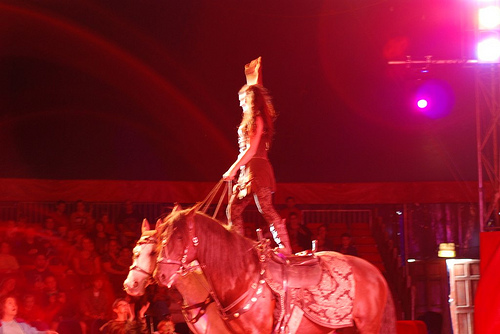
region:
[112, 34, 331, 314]
woman standing on the horses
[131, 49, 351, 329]
woman standing on the horses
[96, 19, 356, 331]
woman standing on the horses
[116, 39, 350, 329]
woman standing on the horses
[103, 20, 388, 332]
woman standing on the horses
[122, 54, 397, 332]
Costumed woman standing on backs of two horses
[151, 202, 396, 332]
Brown horse wearing elaborate tack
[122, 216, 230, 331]
White horse with fancy bridle standing behind brown horse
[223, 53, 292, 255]
Trick rider performing in front of audience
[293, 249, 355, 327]
Blanket with metallic pattern under horse's saddle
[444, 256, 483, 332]
Brown paneled wooden door in background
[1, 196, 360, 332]
Indistinct crowd of people sitting on bleachers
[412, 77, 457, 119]
Spotlight with purple halo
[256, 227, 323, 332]
Special trick rider's saddle on brown horse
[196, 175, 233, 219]
Reins to horses' bridles held in performer's hands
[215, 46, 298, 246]
woman wearing a skirt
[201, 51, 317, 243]
woman with hand raised in the air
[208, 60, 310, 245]
woman wearing boots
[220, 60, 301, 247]
woman standing on two horses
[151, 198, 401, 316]
brown horse with saddle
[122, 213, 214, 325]
white horse in show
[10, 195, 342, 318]
people sitting in the stands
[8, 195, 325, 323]
people watching the woman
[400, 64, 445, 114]
lights on the ceiling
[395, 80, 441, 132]
This is disco light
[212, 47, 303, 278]
This is a person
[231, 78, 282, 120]
Head of a person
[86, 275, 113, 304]
Head of a person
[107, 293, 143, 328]
Head of a person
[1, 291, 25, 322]
Head of a person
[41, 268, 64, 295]
Head of a person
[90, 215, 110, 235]
Head of a person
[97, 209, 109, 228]
Head of a person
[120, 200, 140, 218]
Head of a person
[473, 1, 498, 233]
lights on metal frame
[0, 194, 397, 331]
spectators sitting from stands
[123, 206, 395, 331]
two horses side by side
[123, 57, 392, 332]
woman standing on horses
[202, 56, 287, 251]
woman with hand on reigns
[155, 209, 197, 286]
bridle on horse head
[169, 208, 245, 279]
mane on horse neck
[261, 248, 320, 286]
saddle on back of horse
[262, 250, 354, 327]
blanket on horse under saddle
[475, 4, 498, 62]
two glowing white lights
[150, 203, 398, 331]
A brown circus showhorse.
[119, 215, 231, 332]
A white circus showhorse.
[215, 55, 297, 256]
A circus entertainer stands on top of 2 horses.